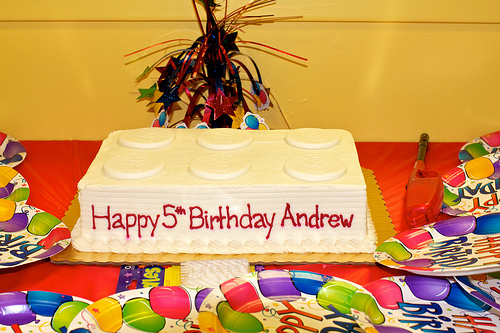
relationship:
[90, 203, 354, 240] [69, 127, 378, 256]
letter on birthday cake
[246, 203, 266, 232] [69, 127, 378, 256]
letter on birthday cake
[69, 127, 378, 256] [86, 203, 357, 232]
birthday cake with writing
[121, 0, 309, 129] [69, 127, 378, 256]
fountain behind birthday cake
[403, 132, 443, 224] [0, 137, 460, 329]
lighter on table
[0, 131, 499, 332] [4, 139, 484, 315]
plate on table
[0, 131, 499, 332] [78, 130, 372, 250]
plate for cake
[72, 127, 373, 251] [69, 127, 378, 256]
frosting on birthday cake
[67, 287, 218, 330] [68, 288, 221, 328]
plate with design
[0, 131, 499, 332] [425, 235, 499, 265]
plate with words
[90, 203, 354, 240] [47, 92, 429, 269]
letter on front of cake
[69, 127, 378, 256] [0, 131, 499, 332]
birthday cake on plate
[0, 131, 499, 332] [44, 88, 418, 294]
plate near cake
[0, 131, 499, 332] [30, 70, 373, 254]
plate near cake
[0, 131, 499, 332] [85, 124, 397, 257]
plate near cake